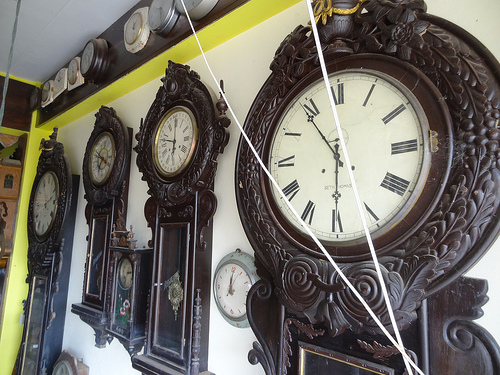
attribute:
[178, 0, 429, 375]
string — white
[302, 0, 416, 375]
string — white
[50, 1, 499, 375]
wall — solid, white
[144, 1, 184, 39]
clock — round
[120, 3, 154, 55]
clock — round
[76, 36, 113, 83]
clock — round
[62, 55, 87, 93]
clock — round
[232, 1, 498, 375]
clock — wall clock, brown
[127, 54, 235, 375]
clock — wall clock, brown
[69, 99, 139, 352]
clock — wall clock, brown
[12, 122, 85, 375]
clock — wall clock, brown